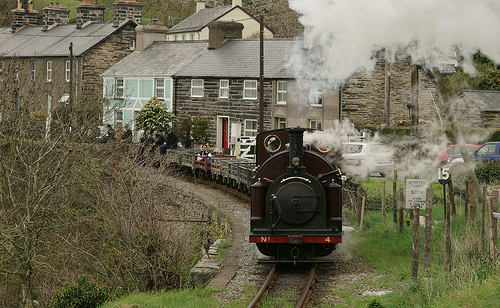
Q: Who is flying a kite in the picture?
A: No one.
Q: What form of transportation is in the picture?
A: A train.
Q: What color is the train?
A: Black.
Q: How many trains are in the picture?
A: One.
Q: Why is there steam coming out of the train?
A: It's a steam engine.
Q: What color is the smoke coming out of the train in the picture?
A: White.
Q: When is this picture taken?
A: Daytime.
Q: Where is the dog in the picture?
A: No where.